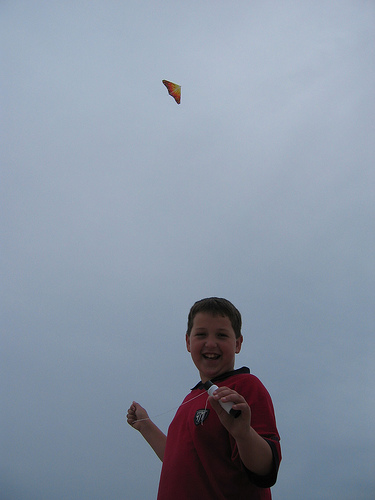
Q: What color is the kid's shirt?
A: Red and black.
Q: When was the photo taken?
A: During the daytime.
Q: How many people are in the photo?
A: One.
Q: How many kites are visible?
A: One.